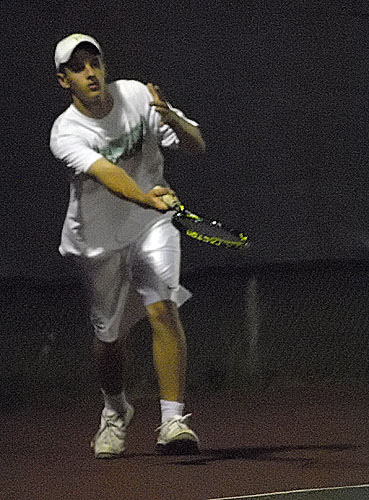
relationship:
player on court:
[54, 19, 225, 496] [17, 291, 359, 498]